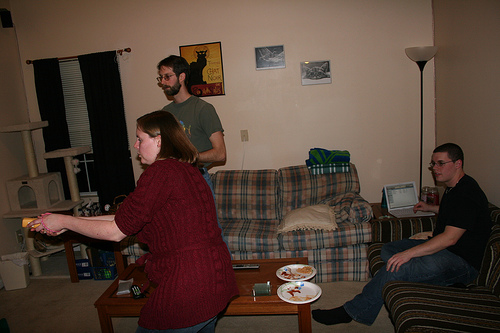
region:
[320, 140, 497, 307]
a man sitting on the couch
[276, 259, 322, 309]
two white plates next to each other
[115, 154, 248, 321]
a maroon sweater that ties around the waist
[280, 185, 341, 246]
a white throw pillow laying on couch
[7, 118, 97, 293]
a play area for cats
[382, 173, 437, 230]
a laptop on the end table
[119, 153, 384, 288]
a plaid couch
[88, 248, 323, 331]
a wood coffee table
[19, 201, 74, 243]
a yellow wii controller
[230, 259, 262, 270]
a black and silver remote control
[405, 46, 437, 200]
Lamp, not being used, in corner of room.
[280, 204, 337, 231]
Tan colored fringed pillow laying on sofa.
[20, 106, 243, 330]
Young woman in red sweater using Wii controller.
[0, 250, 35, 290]
Trash can with plastic bag hanging off edge.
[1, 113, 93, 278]
Cat's play house with toys hanging from one perch.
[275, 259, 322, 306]
Used plates that need to be cleared from table.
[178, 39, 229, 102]
Picture of black cat hanging on wall.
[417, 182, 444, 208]
Two candles in glass containers, not in use.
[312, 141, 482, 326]
Young man watching Wii game, also using laptop.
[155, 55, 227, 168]
Young man in green shirt and glasses watching Wii game intently.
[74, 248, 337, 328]
two plates on the table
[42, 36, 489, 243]
Picture taken indoors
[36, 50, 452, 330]
Three people in a livingroom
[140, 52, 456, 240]
Two men in the room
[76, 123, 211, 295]
One woman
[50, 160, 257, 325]
the woman is wearing a red sweater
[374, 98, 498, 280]
a man is sitting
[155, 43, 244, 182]
a man is standing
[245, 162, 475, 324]
two sofas inthe room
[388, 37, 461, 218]
a lamp in the corner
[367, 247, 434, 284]
the man is wearing jeans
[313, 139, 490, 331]
Man sitting on a couch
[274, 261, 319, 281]
Plate on a table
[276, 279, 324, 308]
Plate on a table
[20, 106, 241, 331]
Woman holding a controller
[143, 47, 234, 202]
Man standing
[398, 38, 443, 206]
Floor lamp that is not on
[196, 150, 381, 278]
Plaid couch with a pillow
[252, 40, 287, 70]
Picture hanging on the wall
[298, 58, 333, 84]
Picture hanging on the wall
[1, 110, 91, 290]
Empty cat tree